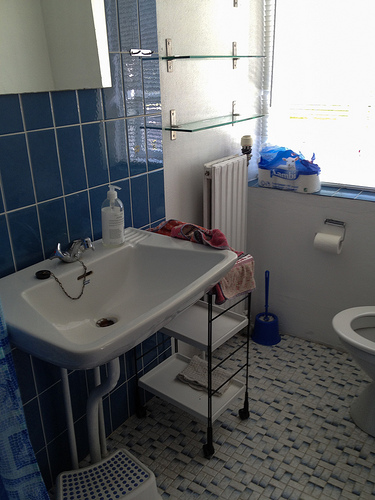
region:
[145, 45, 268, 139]
A pair of glass shelves.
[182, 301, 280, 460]
A rolling set of white shelves.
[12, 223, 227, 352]
A clean white sink.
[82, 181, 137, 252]
A bottle of hand soap.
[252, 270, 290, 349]
A blue toilet brush.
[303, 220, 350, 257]
A roll of toilet paper.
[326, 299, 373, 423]
The edge of a white toilet's seat.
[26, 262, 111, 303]
The sink's stopper on a chain.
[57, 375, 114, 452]
Pipes providing water to the sink.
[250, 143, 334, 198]
Extra rolls of toilet paper.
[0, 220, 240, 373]
A WHITE BATHROOM SINK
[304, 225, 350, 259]
A ROLL OF TOILET PAPER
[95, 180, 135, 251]
A PLASTIC BOTTLE OF HAND SOAP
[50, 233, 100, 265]
A STAINLESS STEELE SINK FAUCET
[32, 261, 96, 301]
A BATHROOM SINK PLUG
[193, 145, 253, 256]
A BATHROOM RADIATOR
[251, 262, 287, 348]
A BLUE TOILET BRUSH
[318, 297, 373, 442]
A WHITE TOILET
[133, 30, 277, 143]
TWO GLASS SHELVES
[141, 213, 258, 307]
BATHROOM TOWELS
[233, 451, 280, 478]
square tiles on bathroom floor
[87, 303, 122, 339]
large hole in the sink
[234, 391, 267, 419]
black wheels on bathroom tray holder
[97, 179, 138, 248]
small white lotion holder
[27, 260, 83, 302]
black chain and stopper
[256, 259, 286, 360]
toilet brush holder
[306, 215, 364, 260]
white toilet paper holder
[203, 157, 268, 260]
white radiatior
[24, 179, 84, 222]
blue tiles with white lines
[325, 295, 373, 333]
white toilet rim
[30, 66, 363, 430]
bathroom with tiles on floor and wall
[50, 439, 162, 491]
spotted step stool underneath sink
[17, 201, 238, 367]
wide and flat white sink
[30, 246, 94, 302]
sink plug and chain on ledge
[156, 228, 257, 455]
wheeled rack with white trays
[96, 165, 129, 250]
pump bottle of soap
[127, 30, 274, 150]
glass racks attached to wall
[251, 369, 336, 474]
tiles set to look like weaving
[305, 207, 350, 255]
toilet paper hanging from holder on wall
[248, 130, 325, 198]
toilet paper in plastic packaging on sill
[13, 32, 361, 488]
Picture of a bathroom.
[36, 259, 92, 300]
Stopper for sink.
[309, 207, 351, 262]
Toilet paper holder.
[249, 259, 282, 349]
Toilet bowl cleaning brush.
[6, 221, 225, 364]
Square white bathroom sink.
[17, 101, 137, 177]
Blue tile squares on wall.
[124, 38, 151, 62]
Silver hook to hang things on.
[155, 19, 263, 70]
Top glass shelf attached to wall.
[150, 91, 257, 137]
Bottom glass shelf attached to wall.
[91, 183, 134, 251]
Container of hand wash.